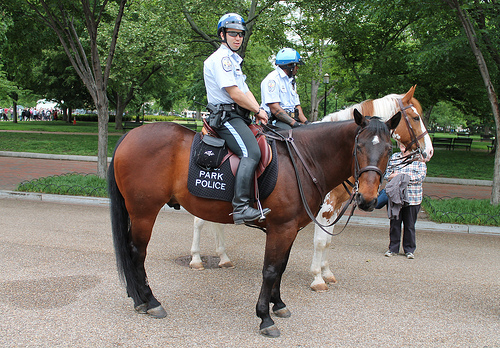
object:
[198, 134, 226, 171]
bag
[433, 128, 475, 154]
bench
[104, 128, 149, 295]
black tail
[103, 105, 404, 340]
horse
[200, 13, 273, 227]
police officer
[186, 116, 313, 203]
saddle